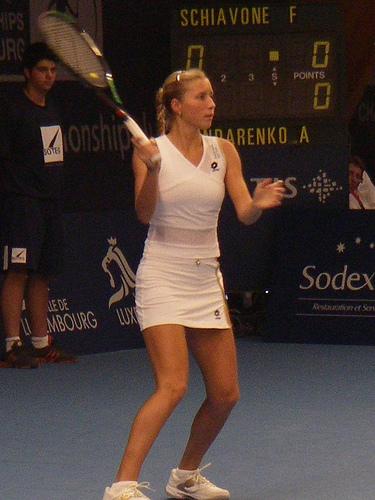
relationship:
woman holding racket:
[122, 60, 289, 500] [32, 6, 163, 173]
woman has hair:
[122, 60, 289, 500] [154, 63, 208, 136]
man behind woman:
[3, 38, 79, 378] [122, 60, 289, 500]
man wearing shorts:
[3, 38, 79, 378] [0, 193, 62, 277]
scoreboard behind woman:
[169, 7, 352, 231] [122, 60, 289, 500]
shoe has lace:
[167, 458, 229, 499] [192, 460, 215, 484]